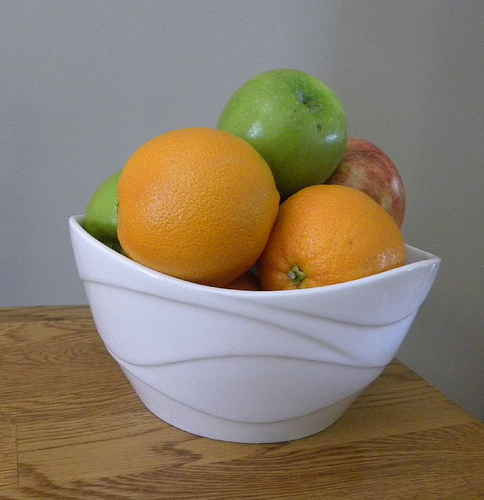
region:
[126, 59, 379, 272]
apples and oranges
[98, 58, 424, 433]
fruit in a white bowl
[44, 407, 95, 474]
a wooden table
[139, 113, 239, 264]
an orange in a white bowl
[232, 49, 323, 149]
a green apple in a white bowl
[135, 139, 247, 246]
an orange sitting in white bowl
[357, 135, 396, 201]
a red apple in a white bowl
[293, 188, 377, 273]
an orange sits in a white bowl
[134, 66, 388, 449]
a group of oranges and apples sitting on a table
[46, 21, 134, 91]
a grey wall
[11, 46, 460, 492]
a small bowl of fruit sitting on a table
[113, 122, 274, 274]
a large orange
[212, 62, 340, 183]
a green Granny Smith apple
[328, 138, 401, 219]
a red apple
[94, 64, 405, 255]
several pieces of fruit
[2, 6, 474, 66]
a gray wall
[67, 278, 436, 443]
a white porcelain bowl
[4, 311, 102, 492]
a wooden table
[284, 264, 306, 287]
a small stem of an orange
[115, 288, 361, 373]
a wavy design on a bowl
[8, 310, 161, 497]
A BROWN WOODEN TABLE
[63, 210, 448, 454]
A WHITE GLASS BOWL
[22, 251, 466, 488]
A WHITE GLASS BOWL ON A TABLE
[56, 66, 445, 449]
A BOWL OF FRUIT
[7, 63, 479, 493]
A BOWL OF FRUIT ON A TABLE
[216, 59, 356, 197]
A GREEN APPLE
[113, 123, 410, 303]
TWO ORANGES IN A BOWL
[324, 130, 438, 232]
A RED APPLE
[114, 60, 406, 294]
TWO ORANGES AND A GREEN APPLE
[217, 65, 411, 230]
A GREEN AND A RED APPLE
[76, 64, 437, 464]
bowl of fruit on table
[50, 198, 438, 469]
wavy design across bowl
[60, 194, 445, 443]
white ceramic bowl with curved edge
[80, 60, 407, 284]
oranges and apples in a container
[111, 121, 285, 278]
porous texture of orange peel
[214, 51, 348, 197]
green apple with light yellow specks across skin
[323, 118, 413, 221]
red apple with yellow undertones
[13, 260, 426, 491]
corner of wooden table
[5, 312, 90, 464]
curls and swirls of wood grain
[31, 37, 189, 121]
grey wall behind table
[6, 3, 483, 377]
light grey wall behind fruit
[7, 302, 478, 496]
brown wooden table top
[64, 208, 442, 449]
white wave pattern bowl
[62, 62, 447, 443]
bowl of mixed fruit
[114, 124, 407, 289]
two whole oranges in bowl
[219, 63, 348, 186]
green apple on top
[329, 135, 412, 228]
edge of red apple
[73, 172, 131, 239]
edge of green apple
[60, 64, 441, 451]
apples and oranges in bowl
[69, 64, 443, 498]
fruit bowl on table